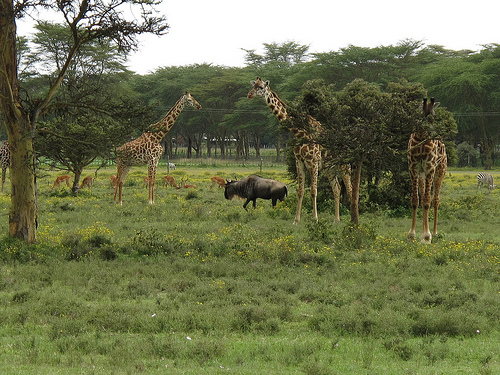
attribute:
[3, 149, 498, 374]
grass — green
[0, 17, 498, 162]
trees — green, large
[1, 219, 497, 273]
flowers — yellow, small, white, scattered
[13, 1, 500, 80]
sky — cloudless, gray, overhead, clear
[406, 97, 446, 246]
giraffe — eating, large, tan, brown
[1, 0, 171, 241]
tree — foreground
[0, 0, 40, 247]
trunk — green, brown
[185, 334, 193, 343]
paper — white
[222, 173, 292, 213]
animal — black, small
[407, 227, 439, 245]
feet — brown, small, white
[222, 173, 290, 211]
wildebeest — dark